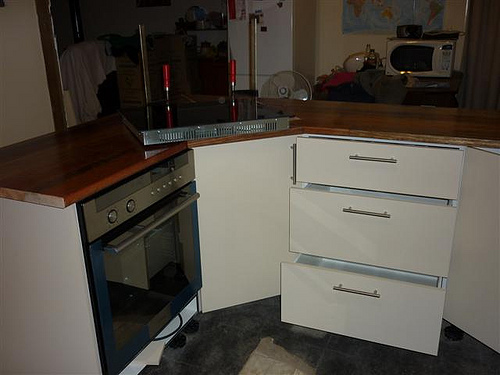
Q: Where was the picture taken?
A: In a kitchen.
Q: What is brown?
A: The countertop.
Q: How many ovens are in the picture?
A: One.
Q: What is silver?
A: The drawer handles.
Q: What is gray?
A: The floor.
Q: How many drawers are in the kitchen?
A: Three.